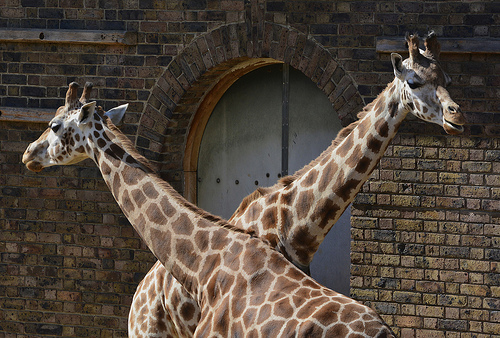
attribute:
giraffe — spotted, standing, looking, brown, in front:
[25, 81, 398, 337]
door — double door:
[184, 55, 351, 337]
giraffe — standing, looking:
[126, 30, 467, 336]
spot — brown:
[151, 225, 171, 267]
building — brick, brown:
[4, 3, 497, 336]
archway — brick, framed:
[119, 14, 376, 335]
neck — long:
[89, 109, 252, 296]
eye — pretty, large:
[50, 123, 67, 132]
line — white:
[0, 29, 499, 46]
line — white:
[1, 109, 120, 122]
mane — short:
[91, 103, 254, 240]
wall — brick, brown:
[3, 2, 495, 337]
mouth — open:
[443, 113, 464, 140]